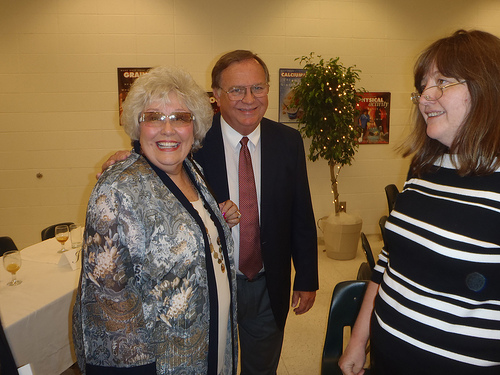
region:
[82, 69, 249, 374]
an older woman with a big smile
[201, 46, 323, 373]
an older man with a big smile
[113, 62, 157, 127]
a multi colored poster framed on the wall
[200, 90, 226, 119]
a multi colored poster framed on the wall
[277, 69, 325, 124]
a multi colored poster framed on the wall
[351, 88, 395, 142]
a multi colored poster framed on the wall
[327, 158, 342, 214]
the trunk of a potted tree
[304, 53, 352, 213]
a string of Christmas lights on potted tree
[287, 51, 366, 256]
a potted tree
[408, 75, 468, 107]
the gold rimmed glasses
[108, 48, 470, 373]
three people smiling in group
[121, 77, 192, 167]
lady with grey hair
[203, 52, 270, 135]
man with grey hair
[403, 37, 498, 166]
lady with brown hair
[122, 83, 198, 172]
lady with square glasses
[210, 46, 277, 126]
man wearing clear glasses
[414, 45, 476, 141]
lady wearing reading glasses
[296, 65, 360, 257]
tree in pot with lights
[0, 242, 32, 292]
glass on table with beverage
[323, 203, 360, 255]
pot for plant on ground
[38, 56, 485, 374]
three people in photograph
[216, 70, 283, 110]
man wearing eye glasses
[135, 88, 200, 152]
woman wearing sunglasses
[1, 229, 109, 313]
two wine glasses on table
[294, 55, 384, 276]
one green tree with white christmas lights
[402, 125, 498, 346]
woman wearing black and white striped shirt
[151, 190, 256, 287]
woman with golden necklace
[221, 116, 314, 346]
man in a red neck tie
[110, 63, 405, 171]
four posters on wall in background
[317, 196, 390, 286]
tree planter is white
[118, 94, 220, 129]
The lady is wearing glasses.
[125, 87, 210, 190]
The woman is smiling at the camera.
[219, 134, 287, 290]
The man is wearing a red time.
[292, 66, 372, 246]
The green plant has lights on it.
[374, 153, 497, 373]
The lady is wearing a black and white striped shirt.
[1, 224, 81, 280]
Wine glasses sitting on the table.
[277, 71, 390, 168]
Pictures posted on the wall.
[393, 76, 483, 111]
The lady with the striped shirt is wearing glasses.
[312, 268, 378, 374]
The lady is standing next to the black chair.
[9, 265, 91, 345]
The table is covered with a white tablecloth.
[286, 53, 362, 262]
a lit up tree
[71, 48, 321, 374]
a man and woman smiling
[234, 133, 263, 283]
a long burgundy tie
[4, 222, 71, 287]
semi filled wine classes on table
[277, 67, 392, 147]
two posters on wall behind tree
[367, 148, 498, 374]
a navy blue and white striped shirt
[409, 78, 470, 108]
glasses hanging down on nose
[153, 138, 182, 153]
red lipstick on lips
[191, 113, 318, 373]
grey pants and navy blue suit jacket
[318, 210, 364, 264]
white planter for tree